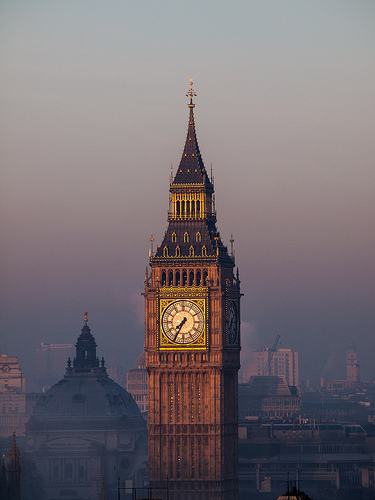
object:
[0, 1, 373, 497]
picture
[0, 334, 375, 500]
city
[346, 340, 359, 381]
building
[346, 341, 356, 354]
dome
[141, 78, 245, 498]
ornatetower,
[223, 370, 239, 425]
shadow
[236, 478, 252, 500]
ground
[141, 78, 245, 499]
architecture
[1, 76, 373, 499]
skyline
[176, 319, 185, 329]
hand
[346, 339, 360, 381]
fog building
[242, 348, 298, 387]
fog building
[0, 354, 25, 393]
fog building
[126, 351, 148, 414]
fog building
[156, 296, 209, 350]
aircraft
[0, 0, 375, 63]
sky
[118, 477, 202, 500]
gate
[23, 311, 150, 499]
building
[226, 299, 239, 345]
angled clock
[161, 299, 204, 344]
clock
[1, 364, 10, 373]
clock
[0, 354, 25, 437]
building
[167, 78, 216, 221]
steeple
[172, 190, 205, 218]
accents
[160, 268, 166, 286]
windows